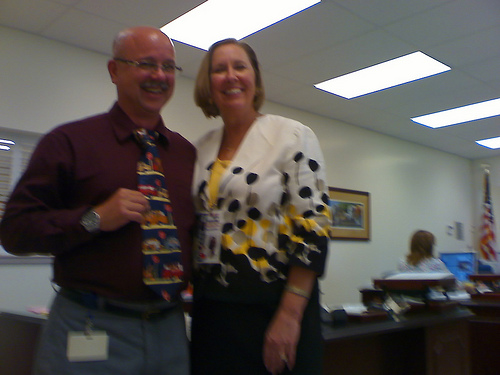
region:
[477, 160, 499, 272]
The American flag in the corner.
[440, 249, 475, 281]
The computer screen the lady is looking at.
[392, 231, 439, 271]
The lady sitting in front of the computer screen.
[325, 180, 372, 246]
The frame on the wall.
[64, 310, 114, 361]
The man's ID clipped to his pants.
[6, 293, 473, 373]
The desk behind the man and woman.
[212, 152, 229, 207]
The yellow shirt under the lady's jacket.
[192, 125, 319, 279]
The white, black and yellow jacket the lady is wearing.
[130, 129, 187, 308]
The tie the man is wearing.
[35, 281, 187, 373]
The gray pants the man is wearing.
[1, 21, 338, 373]
A man and woman posing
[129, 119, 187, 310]
A blue tie with drawings on it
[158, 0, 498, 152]
Lights on the ceiling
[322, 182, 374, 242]
Framed painting on the wall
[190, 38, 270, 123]
Woman has short blonde hair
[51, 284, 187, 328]
A black leather belt with a buckle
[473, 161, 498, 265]
A red, white and blue flag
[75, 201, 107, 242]
Watch around man's wrist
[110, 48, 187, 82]
A pair of eyeglasses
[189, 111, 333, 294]
A white, yellow and black sweater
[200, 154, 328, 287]
The yellow and black design of the woman's jacket.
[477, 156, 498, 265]
The American flag in the right hand corner.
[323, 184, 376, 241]
The frame of art work hanging on the wall.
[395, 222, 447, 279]
The woman sitting in front of the computer screen.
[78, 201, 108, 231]
The watch on the man's wrist.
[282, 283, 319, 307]
The bracelet on the woman's arm.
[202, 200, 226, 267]
The name tag/ID on the front of the woman's jacket.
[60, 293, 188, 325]
The black belt the man is wearing.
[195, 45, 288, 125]
Woman has light brown hair.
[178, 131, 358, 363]
Woman wearing yellow, gray, black, and white top.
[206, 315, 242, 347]
Woman wearing black pants.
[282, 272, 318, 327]
Band around woman's wrist.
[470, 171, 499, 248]
American flag in corner of room.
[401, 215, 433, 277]
Woman has brown hair.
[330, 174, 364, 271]
Framed picture hanging on wall.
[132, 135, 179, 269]
Man wearing colorful tie.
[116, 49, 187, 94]
Glasses on man's face.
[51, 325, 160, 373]
Man wearing gray pants.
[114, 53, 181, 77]
The glasses the man is wearing.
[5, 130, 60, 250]
The window behind the man.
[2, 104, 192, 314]
The burgundy shirt the man is wearing.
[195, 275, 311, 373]
The black skirt the lady is wearing.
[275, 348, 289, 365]
The ring on the lady's finger.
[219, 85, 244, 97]
The lady's mouth and teeth.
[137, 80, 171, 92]
The moustache of the man.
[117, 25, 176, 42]
The man's bald head.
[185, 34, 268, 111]
The lady's short blonde hair.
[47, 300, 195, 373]
The pants the man is wearing.